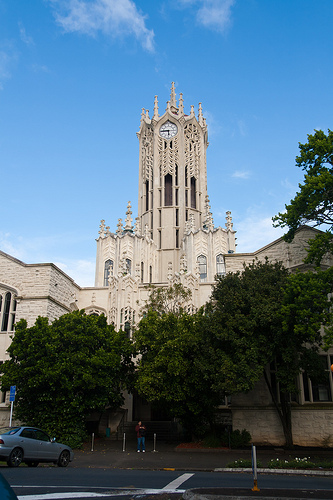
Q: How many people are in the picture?
A: One.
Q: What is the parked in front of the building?
A: Car.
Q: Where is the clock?
A: On the building.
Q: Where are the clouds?
A: The sky.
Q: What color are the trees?
A: Green.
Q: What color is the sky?
A: Blue.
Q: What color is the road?
A: Black.